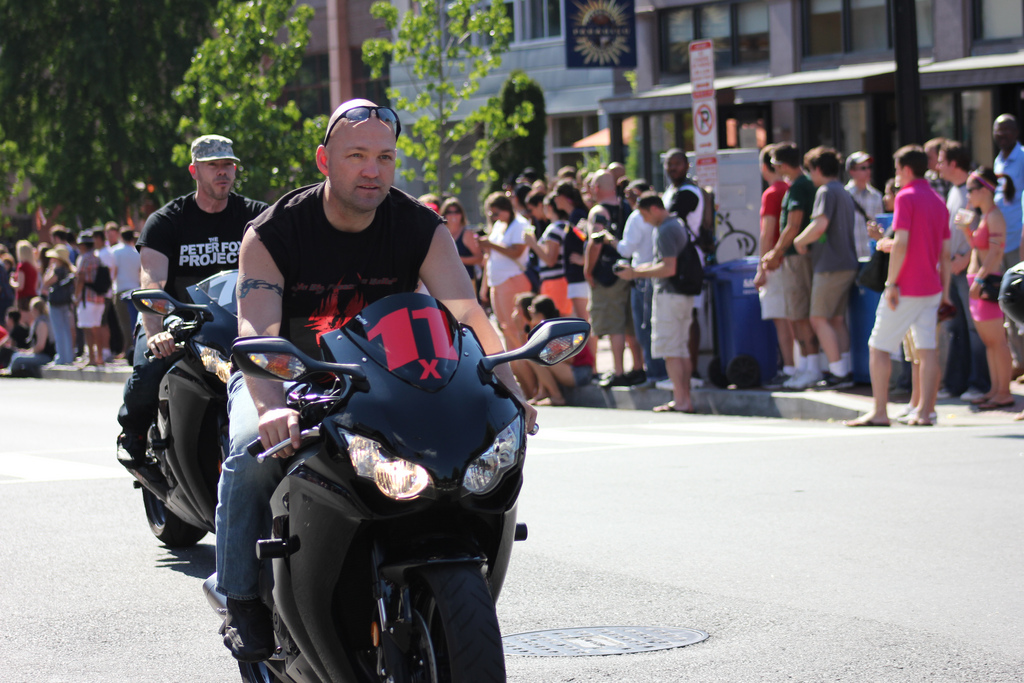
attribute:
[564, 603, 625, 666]
manhole — sealed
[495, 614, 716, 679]
lid — metal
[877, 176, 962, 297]
shirt — red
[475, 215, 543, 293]
top — white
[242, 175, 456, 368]
tank — black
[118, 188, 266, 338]
shirt — black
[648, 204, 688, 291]
shirt — gray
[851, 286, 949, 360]
shorts — white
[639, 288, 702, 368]
shorts — white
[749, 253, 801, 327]
shorts — white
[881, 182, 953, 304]
shirt — pink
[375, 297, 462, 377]
number — red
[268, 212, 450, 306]
shirt — black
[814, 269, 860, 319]
shorts — beige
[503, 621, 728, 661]
manhole cover — metal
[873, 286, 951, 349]
shorts — white